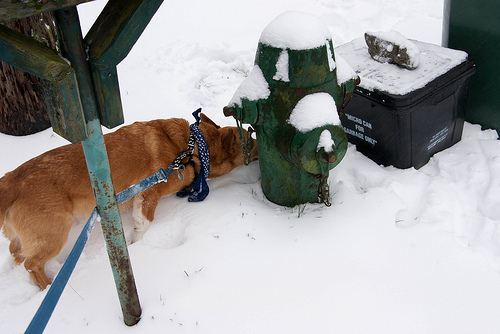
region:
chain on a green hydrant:
[232, 120, 259, 167]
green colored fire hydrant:
[221, 14, 363, 219]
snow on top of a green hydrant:
[256, 10, 336, 54]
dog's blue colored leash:
[16, 157, 178, 327]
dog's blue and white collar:
[178, 114, 213, 203]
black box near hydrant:
[321, 28, 478, 175]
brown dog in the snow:
[0, 120, 267, 291]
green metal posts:
[3, 2, 169, 327]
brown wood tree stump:
[0, 0, 83, 130]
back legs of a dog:
[3, 178, 56, 294]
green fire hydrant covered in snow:
[228, 2, 358, 224]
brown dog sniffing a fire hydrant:
[173, 34, 314, 240]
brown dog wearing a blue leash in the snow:
[8, 110, 254, 259]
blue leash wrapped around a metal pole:
[76, 173, 141, 250]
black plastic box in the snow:
[338, 17, 498, 178]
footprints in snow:
[399, 167, 499, 269]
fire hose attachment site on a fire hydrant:
[277, 105, 357, 209]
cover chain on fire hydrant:
[222, 110, 259, 174]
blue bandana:
[183, 115, 213, 207]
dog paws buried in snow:
[5, 239, 63, 299]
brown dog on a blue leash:
[4, 112, 258, 330]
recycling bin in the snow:
[244, 16, 486, 208]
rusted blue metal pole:
[36, 7, 163, 332]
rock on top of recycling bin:
[333, 35, 471, 170]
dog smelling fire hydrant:
[153, 17, 348, 238]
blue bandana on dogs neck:
[178, 106, 261, 206]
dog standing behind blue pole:
[2, 118, 287, 305]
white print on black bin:
[332, 22, 464, 168]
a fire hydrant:
[234, 23, 364, 208]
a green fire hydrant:
[234, 17, 354, 217]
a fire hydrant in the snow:
[230, 19, 365, 229]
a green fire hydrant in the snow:
[223, 19, 373, 208]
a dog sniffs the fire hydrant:
[19, 96, 261, 291]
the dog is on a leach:
[11, 86, 257, 319]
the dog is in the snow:
[6, 104, 267, 294]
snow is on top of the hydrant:
[227, 17, 355, 224]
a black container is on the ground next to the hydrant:
[339, 36, 469, 171]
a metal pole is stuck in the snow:
[44, 22, 156, 327]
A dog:
[15, 97, 280, 272]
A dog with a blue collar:
[0, 91, 272, 298]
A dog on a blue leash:
[0, 89, 282, 317]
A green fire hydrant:
[231, 7, 351, 238]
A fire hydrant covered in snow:
[226, 11, 352, 255]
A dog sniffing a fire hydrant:
[0, 51, 363, 261]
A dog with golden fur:
[0, 78, 280, 273]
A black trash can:
[313, 0, 477, 231]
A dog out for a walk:
[2, 18, 431, 270]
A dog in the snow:
[0, 104, 380, 306]